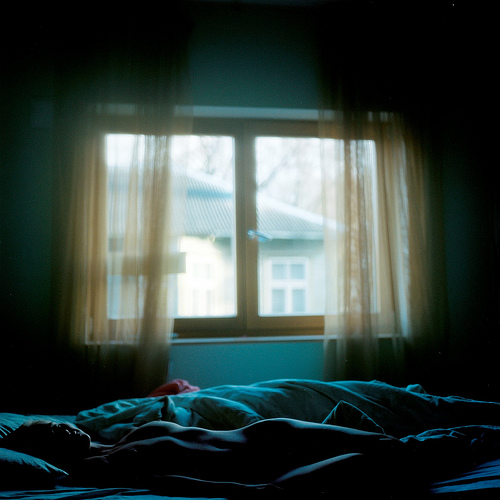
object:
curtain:
[49, 0, 194, 394]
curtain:
[319, 0, 449, 383]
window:
[100, 116, 410, 334]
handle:
[247, 230, 271, 240]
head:
[3, 419, 93, 470]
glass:
[254, 135, 379, 318]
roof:
[105, 166, 344, 246]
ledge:
[92, 332, 406, 351]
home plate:
[244, 315, 381, 335]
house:
[105, 163, 345, 319]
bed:
[0, 377, 499, 499]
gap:
[243, 131, 247, 328]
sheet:
[19, 487, 136, 499]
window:
[259, 257, 319, 321]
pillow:
[1, 411, 71, 490]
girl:
[6, 417, 481, 491]